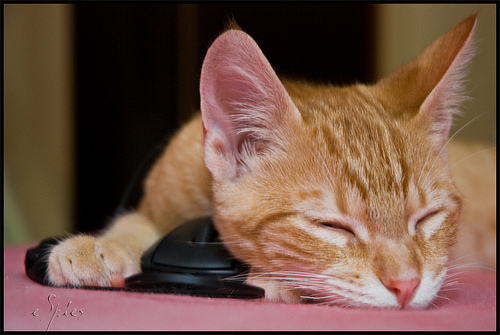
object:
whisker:
[221, 269, 379, 308]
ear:
[198, 29, 303, 186]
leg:
[98, 112, 213, 254]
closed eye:
[316, 220, 358, 238]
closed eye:
[413, 208, 442, 231]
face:
[215, 129, 460, 309]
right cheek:
[212, 174, 312, 272]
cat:
[47, 10, 497, 311]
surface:
[3, 242, 495, 331]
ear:
[373, 9, 480, 145]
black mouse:
[123, 214, 266, 299]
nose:
[371, 238, 423, 309]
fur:
[317, 102, 383, 190]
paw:
[47, 235, 142, 288]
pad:
[1, 242, 495, 330]